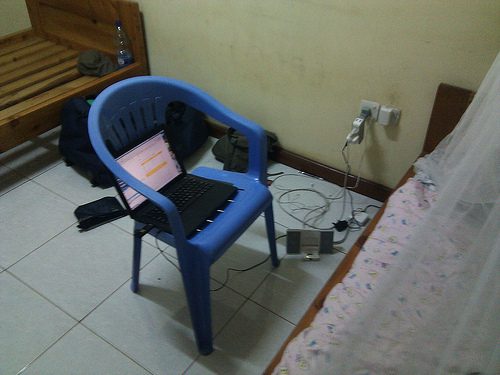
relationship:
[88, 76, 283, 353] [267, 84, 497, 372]
chair in front of bed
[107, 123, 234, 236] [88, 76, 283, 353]
laptop on chair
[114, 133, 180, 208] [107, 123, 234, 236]
screen of laptop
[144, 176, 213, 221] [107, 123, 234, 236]
keyboard black for laptop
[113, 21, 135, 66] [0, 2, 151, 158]
bottle on a bed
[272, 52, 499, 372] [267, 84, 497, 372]
tulle over bed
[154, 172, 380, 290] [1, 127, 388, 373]
wires on floor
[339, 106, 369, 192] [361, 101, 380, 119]
plugs plugged into outlet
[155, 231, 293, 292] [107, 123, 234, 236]
wire plugged into laptop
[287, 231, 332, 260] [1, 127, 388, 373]
stereo sitting on floor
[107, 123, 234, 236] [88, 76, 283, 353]
laptop on a blue chair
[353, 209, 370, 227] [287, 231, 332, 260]
ipod plugged into stereo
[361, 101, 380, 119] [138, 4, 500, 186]
outlet on wall